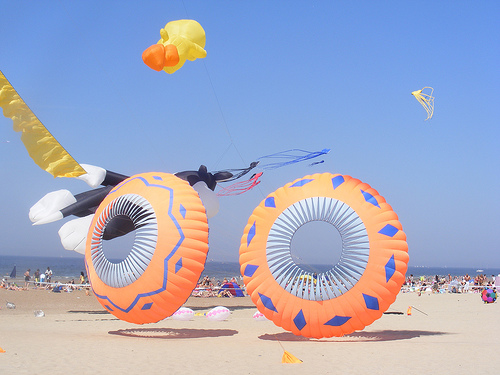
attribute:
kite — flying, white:
[409, 76, 448, 134]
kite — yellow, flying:
[133, 12, 207, 73]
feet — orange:
[143, 38, 187, 77]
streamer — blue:
[264, 148, 311, 158]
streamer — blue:
[267, 160, 311, 166]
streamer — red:
[237, 183, 257, 194]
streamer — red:
[222, 183, 247, 191]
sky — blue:
[4, 1, 499, 273]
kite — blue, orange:
[252, 168, 406, 330]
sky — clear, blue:
[249, 46, 377, 131]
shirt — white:
[43, 268, 53, 277]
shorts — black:
[22, 274, 31, 284]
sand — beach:
[207, 337, 269, 373]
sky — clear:
[265, 12, 376, 133]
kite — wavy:
[260, 145, 336, 166]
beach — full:
[424, 272, 494, 294]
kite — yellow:
[409, 78, 445, 132]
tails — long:
[424, 80, 435, 126]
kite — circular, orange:
[234, 159, 420, 348]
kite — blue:
[256, 145, 331, 169]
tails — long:
[262, 145, 318, 171]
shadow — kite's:
[104, 322, 243, 340]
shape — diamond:
[359, 290, 383, 314]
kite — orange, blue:
[235, 166, 407, 333]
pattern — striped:
[296, 200, 327, 219]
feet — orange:
[139, 41, 181, 73]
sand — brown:
[27, 299, 490, 361]